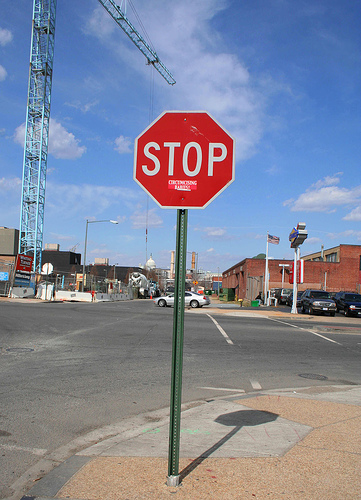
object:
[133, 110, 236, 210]
sign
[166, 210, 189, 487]
pole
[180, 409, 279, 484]
shadow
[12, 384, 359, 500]
sidewalk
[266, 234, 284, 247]
flag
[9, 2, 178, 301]
crane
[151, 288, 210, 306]
car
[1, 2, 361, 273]
sky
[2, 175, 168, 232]
clouds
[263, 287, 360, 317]
cars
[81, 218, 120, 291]
light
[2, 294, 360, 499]
street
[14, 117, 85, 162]
cloud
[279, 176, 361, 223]
cloud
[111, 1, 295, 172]
cloud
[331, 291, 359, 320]
car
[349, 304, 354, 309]
headlight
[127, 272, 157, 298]
mixer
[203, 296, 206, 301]
tail light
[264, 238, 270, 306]
pole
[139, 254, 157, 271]
dome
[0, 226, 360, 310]
building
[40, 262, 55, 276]
sign back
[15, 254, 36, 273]
sign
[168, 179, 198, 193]
sticker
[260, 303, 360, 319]
parking lot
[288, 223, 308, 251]
sign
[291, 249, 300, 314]
pole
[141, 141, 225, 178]
letters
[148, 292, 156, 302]
cone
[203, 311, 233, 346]
line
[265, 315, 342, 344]
line